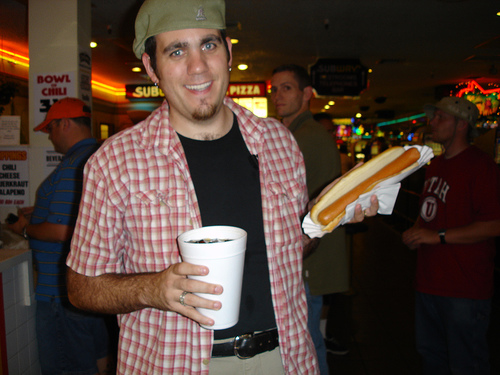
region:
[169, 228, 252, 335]
large white disposable cup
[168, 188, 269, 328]
white cup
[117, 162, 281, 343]
white cup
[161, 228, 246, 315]
white cup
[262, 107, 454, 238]
a long hot dog in the man's hand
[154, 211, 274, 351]
a white cut in the man's hand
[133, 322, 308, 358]
the black belt the man is wearing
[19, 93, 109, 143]
a red hat on a man's head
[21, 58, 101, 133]
a sign that says bowl of chili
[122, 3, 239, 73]
the man's hat that is holding a hot dog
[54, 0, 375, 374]
a man wearing a black shirt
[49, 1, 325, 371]
a man wearing a red and white striped shirt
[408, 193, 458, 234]
the letter U in a circle on a man's shirt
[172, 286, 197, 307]
the wedding band on the man's hand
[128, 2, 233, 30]
man wearing green hat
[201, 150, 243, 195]
Man wearing black shirt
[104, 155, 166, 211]
man wearing checkered shirt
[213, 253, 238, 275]
Large White styrafoam cup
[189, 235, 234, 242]
Soda and ice in cup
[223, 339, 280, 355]
Man wearing black belt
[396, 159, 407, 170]
Hotdog in long bun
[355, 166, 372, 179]
Long bun with hotdog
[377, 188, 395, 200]
White paper towel under bun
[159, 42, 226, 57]
Man has blue eyes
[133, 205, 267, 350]
large white cup with a dark beverage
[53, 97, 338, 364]
man in a red plaid shirt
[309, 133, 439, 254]
a large hot dog in a mans hand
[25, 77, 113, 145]
man wearing a red hat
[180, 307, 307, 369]
black belt holding pants up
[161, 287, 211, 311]
a wedding ring on a mans finger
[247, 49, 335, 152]
a man standing in line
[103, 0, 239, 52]
a tan hat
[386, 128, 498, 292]
a red tee shirt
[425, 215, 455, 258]
a man wearing a black watch